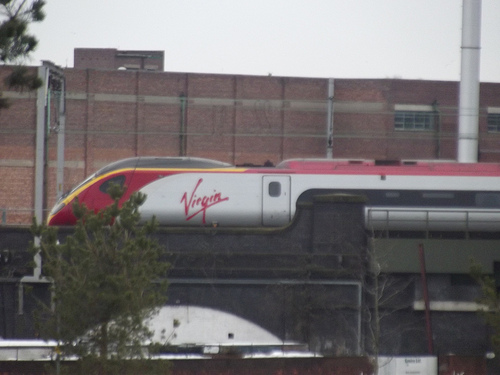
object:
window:
[384, 192, 400, 199]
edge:
[361, 78, 431, 91]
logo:
[180, 178, 230, 223]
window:
[98, 175, 125, 191]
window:
[473, 190, 498, 209]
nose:
[45, 156, 134, 228]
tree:
[33, 188, 178, 374]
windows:
[379, 191, 417, 207]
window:
[389, 112, 435, 129]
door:
[262, 175, 291, 228]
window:
[269, 181, 280, 196]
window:
[420, 185, 459, 207]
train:
[43, 154, 499, 276]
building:
[61, 46, 388, 155]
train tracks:
[2, 283, 485, 339]